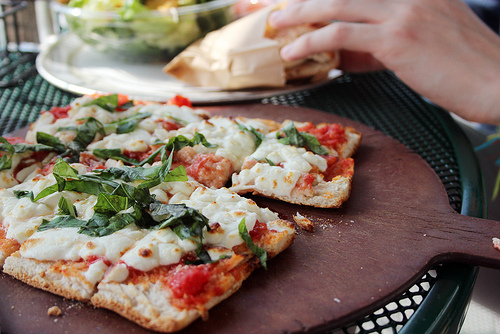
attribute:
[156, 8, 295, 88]
wrapper — paper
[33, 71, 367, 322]
pizza — crispy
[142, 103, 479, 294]
board — grated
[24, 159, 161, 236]
spinach — green, fresh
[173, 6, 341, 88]
bag — paper, brown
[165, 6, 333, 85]
bag — brown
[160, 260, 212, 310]
tomato — chunk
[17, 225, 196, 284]
cheese — melted, mozzarella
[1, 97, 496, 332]
tray — Wooden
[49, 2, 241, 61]
bowl — blurred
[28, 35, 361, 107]
dinner plate — large, white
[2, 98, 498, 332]
board — wood, dark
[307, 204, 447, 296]
platter — brown, wooden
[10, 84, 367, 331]
pizza — rectangular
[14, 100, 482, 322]
board — wooden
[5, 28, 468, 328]
table — green, metal